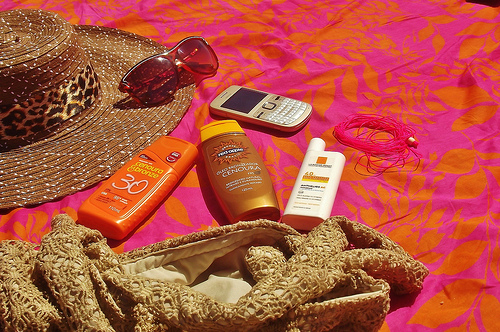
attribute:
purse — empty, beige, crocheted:
[1, 209, 425, 330]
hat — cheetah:
[7, 9, 203, 223]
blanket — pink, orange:
[233, 1, 497, 205]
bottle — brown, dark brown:
[199, 120, 280, 225]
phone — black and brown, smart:
[203, 78, 318, 138]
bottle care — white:
[280, 133, 349, 224]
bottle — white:
[282, 136, 346, 230]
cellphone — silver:
[206, 82, 315, 138]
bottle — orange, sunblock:
[76, 130, 198, 233]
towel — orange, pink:
[0, 0, 500, 330]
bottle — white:
[282, 135, 343, 223]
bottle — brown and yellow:
[77, 127, 200, 244]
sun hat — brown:
[2, 6, 213, 216]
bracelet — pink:
[332, 111, 419, 175]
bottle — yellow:
[192, 116, 285, 222]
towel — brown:
[8, 2, 497, 240]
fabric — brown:
[1, 223, 429, 330]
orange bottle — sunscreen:
[77, 136, 195, 226]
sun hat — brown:
[1, 9, 195, 206]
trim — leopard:
[6, 90, 82, 121]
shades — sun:
[115, 37, 220, 106]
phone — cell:
[210, 79, 332, 135]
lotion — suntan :
[60, 114, 353, 237]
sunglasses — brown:
[116, 34, 222, 112]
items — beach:
[4, 20, 443, 330]